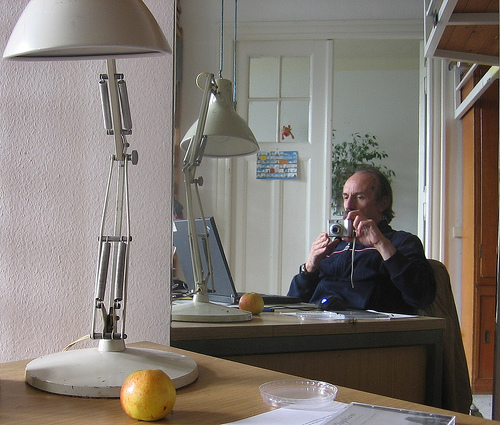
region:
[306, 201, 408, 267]
camera in both hands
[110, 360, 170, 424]
large yellow and red grapefruit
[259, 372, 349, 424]
glass bowl on table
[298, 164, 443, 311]
man wearing dark blue pull over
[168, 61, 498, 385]
large mirror on the wall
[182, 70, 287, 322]
pixar style white lamp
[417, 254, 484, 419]
jacket hanging on chair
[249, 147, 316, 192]
blue sign on door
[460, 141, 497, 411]
tall wood cabinet in background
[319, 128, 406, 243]
green ficus tree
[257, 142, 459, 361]
man sitting on chair holding camera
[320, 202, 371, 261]
man holding silver camera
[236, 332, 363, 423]
plastic top on table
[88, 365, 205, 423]
apple on the table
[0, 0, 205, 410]
white steel lamp on table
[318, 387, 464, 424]
cd cover on table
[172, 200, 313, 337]
black lap top on table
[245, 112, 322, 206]
picture on door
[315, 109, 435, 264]
pot plant in door way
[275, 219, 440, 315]
man wearing navy blue sweater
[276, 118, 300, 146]
Window decal on closed door window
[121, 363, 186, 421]
Apple on desk next to lamp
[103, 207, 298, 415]
Mirror reflection showing apple on the actual desk as well as in the mirror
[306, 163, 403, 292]
Man taking selfie in mirror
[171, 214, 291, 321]
Laptop shown in mirror reflection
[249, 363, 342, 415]
plastic lid on desk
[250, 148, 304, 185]
Kid's painting on closed door under window decal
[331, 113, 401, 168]
plant seen through open portion of the door in the mirror reflection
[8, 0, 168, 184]
lamp fixture sitting on desk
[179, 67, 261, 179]
reverse view of lamp fixture as seen through the mirror reflection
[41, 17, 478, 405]
The picture of a man in a mirror.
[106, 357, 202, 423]
Apple laying on table.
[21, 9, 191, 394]
A silver adjustable lamp.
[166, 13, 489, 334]
A large square mirror.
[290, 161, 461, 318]
Reflection of man in mirror.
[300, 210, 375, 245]
Reflection of a camera in mirror.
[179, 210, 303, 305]
Reflection of a laptop in mirror.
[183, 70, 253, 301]
Reflection of an adjustable lamp in mirror.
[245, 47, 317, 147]
Relfection of panes of glass in door.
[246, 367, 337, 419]
A clear plastic top.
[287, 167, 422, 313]
reflection of man photographing his reflection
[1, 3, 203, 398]
desk lamp on desk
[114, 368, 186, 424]
apple on desk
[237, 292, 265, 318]
reflection of apple on desk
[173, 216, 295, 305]
reflection of laptop in mirror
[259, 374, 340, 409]
empty ashtray on desk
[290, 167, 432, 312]
reflection of balding man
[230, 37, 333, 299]
reflection of door with glass panes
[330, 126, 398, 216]
large houseplant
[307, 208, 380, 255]
reflection of hands hold camera